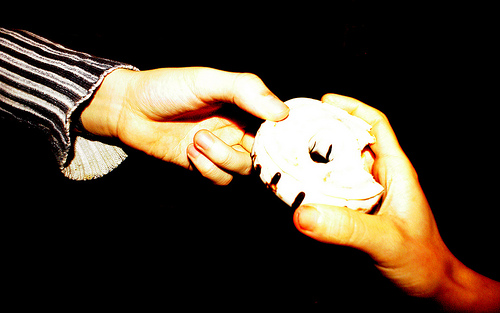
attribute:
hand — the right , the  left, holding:
[114, 56, 283, 211]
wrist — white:
[33, 39, 155, 189]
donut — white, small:
[236, 93, 397, 213]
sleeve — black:
[45, 45, 145, 155]